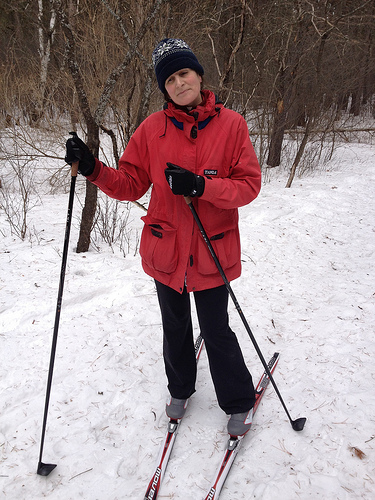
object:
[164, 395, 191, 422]
boot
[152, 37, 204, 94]
wool hat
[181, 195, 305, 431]
pole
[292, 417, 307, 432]
disc support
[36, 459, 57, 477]
disc support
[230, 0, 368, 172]
tree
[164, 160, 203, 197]
glove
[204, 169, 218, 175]
logo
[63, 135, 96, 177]
glove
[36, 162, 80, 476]
pole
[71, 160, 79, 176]
handle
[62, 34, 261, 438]
skier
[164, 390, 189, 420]
ski boot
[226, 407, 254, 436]
ski boot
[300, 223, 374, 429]
snow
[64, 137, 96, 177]
gloved hand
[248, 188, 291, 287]
snow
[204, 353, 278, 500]
skis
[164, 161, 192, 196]
hand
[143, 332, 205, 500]
skis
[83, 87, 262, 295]
coat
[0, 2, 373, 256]
woods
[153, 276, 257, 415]
pants